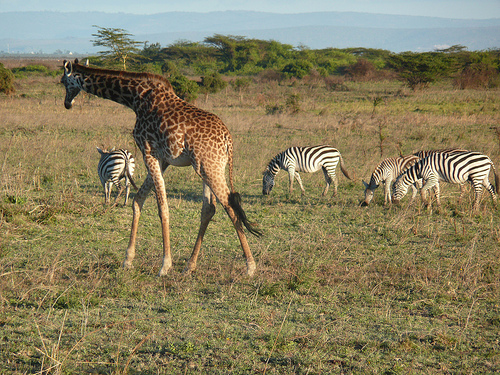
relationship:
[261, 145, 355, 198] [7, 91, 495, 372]
animal eating grass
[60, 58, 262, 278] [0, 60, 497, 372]
animal walking in field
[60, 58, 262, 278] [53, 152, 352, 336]
animal walking in field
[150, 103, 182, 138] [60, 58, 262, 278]
spots on animal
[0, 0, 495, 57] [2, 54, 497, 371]
mountains overlook fields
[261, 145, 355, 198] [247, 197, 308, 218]
animal eating grass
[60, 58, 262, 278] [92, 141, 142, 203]
animal taller than zebra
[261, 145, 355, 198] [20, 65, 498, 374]
animal eating grass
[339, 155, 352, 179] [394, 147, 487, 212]
long tail on zebra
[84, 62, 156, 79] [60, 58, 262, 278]
brown mane of animal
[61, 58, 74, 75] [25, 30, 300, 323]
ear of giraffe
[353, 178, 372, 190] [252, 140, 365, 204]
ear of zebra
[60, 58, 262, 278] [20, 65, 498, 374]
animal on grass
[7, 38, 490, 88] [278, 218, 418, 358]
trees on ground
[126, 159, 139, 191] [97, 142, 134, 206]
long tail of zebra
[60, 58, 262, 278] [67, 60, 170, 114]
animal horizontally bending neck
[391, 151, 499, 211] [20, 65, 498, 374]
animal eating grass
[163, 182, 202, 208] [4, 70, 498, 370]
shadow on ground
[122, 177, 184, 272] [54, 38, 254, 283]
legs on giraffe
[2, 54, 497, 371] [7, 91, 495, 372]
fields covered in grass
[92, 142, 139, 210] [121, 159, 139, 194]
animal has long tail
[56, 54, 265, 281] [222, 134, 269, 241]
animal has long tail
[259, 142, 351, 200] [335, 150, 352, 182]
animal has long tail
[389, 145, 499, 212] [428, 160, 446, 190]
animal has long tail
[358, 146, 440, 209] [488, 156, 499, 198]
animal has long tail